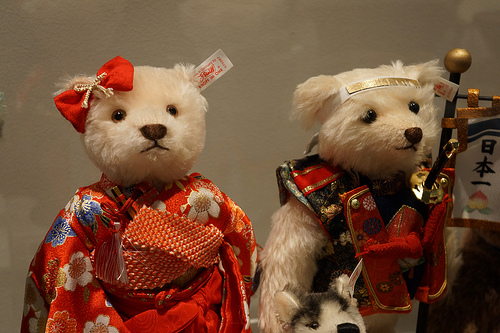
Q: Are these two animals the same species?
A: No, they are wolves and bears.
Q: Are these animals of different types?
A: Yes, they are wolves and bears.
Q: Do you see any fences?
A: No, there are no fences.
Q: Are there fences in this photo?
A: No, there are no fences.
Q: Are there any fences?
A: No, there are no fences.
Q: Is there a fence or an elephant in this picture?
A: No, there are no fences or elephants.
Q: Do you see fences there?
A: No, there are no fences.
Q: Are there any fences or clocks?
A: No, there are no fences or clocks.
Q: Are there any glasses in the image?
A: No, there are no glasses.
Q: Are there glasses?
A: No, there are no glasses.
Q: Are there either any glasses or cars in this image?
A: No, there are no glasses or cars.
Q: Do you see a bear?
A: Yes, there is a bear.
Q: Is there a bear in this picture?
A: Yes, there is a bear.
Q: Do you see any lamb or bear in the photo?
A: Yes, there is a bear.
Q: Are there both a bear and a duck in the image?
A: No, there is a bear but no ducks.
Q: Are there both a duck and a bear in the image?
A: No, there is a bear but no ducks.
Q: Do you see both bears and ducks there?
A: No, there is a bear but no ducks.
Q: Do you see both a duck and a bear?
A: No, there is a bear but no ducks.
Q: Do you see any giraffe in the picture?
A: No, there are no giraffes.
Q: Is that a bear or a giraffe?
A: That is a bear.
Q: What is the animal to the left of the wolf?
A: The animal is a bear.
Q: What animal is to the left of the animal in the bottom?
A: The animal is a bear.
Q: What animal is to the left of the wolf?
A: The animal is a bear.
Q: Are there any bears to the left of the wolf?
A: Yes, there is a bear to the left of the wolf.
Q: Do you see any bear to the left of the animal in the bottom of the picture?
A: Yes, there is a bear to the left of the wolf.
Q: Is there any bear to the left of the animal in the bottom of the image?
A: Yes, there is a bear to the left of the wolf.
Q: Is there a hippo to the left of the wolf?
A: No, there is a bear to the left of the wolf.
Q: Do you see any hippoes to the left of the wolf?
A: No, there is a bear to the left of the wolf.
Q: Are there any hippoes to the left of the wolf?
A: No, there is a bear to the left of the wolf.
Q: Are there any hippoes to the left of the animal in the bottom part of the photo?
A: No, there is a bear to the left of the wolf.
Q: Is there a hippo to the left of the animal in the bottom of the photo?
A: No, there is a bear to the left of the wolf.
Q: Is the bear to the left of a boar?
A: No, the bear is to the left of a wolf.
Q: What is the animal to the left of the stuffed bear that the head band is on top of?
A: The animal is a bear.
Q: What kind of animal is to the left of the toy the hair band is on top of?
A: The animal is a bear.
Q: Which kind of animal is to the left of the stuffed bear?
A: The animal is a bear.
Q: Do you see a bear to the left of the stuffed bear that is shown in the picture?
A: Yes, there is a bear to the left of the stuffed bear.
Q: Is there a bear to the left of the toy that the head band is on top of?
A: Yes, there is a bear to the left of the stuffed bear.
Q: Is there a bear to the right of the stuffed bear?
A: No, the bear is to the left of the stuffed bear.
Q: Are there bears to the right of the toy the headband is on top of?
A: No, the bear is to the left of the stuffed bear.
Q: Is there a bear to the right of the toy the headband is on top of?
A: No, the bear is to the left of the stuffed bear.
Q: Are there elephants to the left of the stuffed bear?
A: No, there is a bear to the left of the stuffed bear.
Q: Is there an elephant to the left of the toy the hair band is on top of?
A: No, there is a bear to the left of the stuffed bear.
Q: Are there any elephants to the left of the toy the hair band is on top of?
A: No, there is a bear to the left of the stuffed bear.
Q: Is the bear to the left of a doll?
A: No, the bear is to the left of a stuffed bear.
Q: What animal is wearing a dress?
A: The bear is wearing a dress.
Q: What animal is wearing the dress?
A: The bear is wearing a dress.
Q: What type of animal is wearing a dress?
A: The animal is a bear.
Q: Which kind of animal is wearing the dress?
A: The animal is a bear.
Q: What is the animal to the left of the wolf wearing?
A: The bear is wearing a dress.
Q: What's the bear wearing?
A: The bear is wearing a dress.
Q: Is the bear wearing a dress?
A: Yes, the bear is wearing a dress.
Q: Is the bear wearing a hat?
A: No, the bear is wearing a dress.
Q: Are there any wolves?
A: Yes, there is a wolf.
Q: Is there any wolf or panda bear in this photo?
A: Yes, there is a wolf.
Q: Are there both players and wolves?
A: No, there is a wolf but no players.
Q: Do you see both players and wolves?
A: No, there is a wolf but no players.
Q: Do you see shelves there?
A: No, there are no shelves.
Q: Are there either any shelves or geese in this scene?
A: No, there are no shelves or geese.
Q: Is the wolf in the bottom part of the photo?
A: Yes, the wolf is in the bottom of the image.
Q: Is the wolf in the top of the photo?
A: No, the wolf is in the bottom of the image.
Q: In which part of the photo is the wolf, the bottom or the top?
A: The wolf is in the bottom of the image.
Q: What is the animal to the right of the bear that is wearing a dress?
A: The animal is a wolf.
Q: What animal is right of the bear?
A: The animal is a wolf.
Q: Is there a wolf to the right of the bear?
A: Yes, there is a wolf to the right of the bear.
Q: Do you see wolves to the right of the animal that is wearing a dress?
A: Yes, there is a wolf to the right of the bear.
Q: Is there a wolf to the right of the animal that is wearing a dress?
A: Yes, there is a wolf to the right of the bear.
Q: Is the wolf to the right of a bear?
A: Yes, the wolf is to the right of a bear.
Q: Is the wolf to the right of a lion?
A: No, the wolf is to the right of a bear.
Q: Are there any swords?
A: Yes, there is a sword.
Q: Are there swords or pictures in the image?
A: Yes, there is a sword.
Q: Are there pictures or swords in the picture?
A: Yes, there is a sword.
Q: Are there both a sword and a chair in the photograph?
A: No, there is a sword but no chairs.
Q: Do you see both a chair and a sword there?
A: No, there is a sword but no chairs.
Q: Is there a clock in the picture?
A: No, there are no clocks.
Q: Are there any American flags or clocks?
A: No, there are no clocks or American flags.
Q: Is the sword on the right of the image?
A: Yes, the sword is on the right of the image.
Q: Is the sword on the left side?
A: No, the sword is on the right of the image.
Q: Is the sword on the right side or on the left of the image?
A: The sword is on the right of the image.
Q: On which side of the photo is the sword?
A: The sword is on the right of the image.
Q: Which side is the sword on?
A: The sword is on the right of the image.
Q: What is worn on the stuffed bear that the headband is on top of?
A: The sword is worn on the stuffed bear.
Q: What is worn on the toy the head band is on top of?
A: The sword is worn on the stuffed bear.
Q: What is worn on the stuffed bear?
A: The sword is worn on the stuffed bear.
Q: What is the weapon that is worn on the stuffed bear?
A: The weapon is a sword.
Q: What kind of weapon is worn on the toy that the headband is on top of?
A: The weapon is a sword.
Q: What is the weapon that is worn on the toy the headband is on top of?
A: The weapon is a sword.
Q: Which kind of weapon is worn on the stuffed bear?
A: The weapon is a sword.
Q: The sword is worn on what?
A: The sword is worn on the stuffed bear.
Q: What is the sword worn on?
A: The sword is worn on the stuffed bear.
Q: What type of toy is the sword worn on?
A: The sword is worn on the stuffed bear.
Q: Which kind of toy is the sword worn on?
A: The sword is worn on the stuffed bear.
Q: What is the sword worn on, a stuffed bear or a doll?
A: The sword is worn on a stuffed bear.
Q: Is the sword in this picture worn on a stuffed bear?
A: Yes, the sword is worn on a stuffed bear.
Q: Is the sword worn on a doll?
A: No, the sword is worn on a stuffed bear.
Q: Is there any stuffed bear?
A: Yes, there is a stuffed bear.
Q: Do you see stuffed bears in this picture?
A: Yes, there is a stuffed bear.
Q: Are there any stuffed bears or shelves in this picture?
A: Yes, there is a stuffed bear.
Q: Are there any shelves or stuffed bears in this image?
A: Yes, there is a stuffed bear.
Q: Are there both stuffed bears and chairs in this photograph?
A: No, there is a stuffed bear but no chairs.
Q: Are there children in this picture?
A: No, there are no children.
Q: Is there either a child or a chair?
A: No, there are no children or chairs.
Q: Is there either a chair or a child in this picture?
A: No, there are no children or chairs.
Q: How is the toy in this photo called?
A: The toy is a stuffed bear.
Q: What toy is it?
A: The toy is a stuffed bear.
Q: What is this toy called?
A: This is a stuffed bear.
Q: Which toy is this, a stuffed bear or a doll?
A: This is a stuffed bear.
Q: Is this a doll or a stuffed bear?
A: This is a stuffed bear.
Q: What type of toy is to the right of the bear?
A: The toy is a stuffed bear.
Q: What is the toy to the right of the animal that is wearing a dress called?
A: The toy is a stuffed bear.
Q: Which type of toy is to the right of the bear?
A: The toy is a stuffed bear.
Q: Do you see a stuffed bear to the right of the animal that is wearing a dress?
A: Yes, there is a stuffed bear to the right of the bear.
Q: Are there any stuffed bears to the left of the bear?
A: No, the stuffed bear is to the right of the bear.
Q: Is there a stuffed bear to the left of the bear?
A: No, the stuffed bear is to the right of the bear.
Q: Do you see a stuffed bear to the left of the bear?
A: No, the stuffed bear is to the right of the bear.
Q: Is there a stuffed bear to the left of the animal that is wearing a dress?
A: No, the stuffed bear is to the right of the bear.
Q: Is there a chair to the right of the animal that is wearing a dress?
A: No, there is a stuffed bear to the right of the bear.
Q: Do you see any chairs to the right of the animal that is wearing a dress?
A: No, there is a stuffed bear to the right of the bear.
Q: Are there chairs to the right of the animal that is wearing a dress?
A: No, there is a stuffed bear to the right of the bear.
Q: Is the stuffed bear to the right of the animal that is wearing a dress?
A: Yes, the stuffed bear is to the right of the bear.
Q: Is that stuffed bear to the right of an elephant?
A: No, the stuffed bear is to the right of the bear.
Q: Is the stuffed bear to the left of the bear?
A: No, the stuffed bear is to the right of the bear.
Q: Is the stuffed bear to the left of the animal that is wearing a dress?
A: No, the stuffed bear is to the right of the bear.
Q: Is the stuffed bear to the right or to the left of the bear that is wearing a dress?
A: The stuffed bear is to the right of the bear.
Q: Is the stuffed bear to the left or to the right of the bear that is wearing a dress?
A: The stuffed bear is to the right of the bear.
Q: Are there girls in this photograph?
A: No, there are no girls.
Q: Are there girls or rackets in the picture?
A: No, there are no girls or rackets.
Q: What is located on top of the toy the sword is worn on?
A: The headband is on top of the stuffed bear.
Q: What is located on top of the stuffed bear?
A: The headband is on top of the stuffed bear.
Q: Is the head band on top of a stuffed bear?
A: Yes, the head band is on top of a stuffed bear.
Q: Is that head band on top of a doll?
A: No, the head band is on top of a stuffed bear.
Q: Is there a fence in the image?
A: No, there are no fences.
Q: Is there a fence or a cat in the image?
A: No, there are no fences or cats.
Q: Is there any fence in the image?
A: No, there are no fences.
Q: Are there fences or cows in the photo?
A: No, there are no fences or cows.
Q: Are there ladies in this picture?
A: No, there are no ladies.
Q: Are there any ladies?
A: No, there are no ladies.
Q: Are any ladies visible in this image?
A: No, there are no ladies.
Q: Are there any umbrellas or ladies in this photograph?
A: No, there are no ladies or umbrellas.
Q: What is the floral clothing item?
A: The clothing item is a dress.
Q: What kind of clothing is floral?
A: The clothing is a dress.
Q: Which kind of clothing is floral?
A: The clothing is a dress.